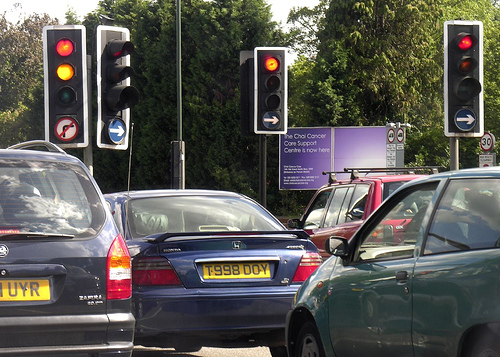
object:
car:
[102, 189, 323, 352]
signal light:
[56, 63, 74, 81]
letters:
[302, 149, 306, 153]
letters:
[8, 282, 16, 296]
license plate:
[203, 262, 272, 279]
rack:
[322, 165, 438, 186]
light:
[106, 233, 131, 300]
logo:
[0, 244, 10, 257]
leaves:
[286, 6, 300, 26]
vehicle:
[0, 147, 136, 356]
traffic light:
[56, 38, 77, 104]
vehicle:
[103, 186, 323, 356]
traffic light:
[94, 20, 137, 155]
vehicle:
[287, 168, 438, 266]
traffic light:
[263, 53, 280, 109]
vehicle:
[282, 167, 499, 357]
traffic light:
[442, 18, 486, 139]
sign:
[278, 122, 405, 190]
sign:
[481, 133, 493, 151]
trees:
[2, 0, 499, 221]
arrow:
[110, 126, 124, 136]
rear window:
[124, 196, 286, 238]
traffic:
[0, 139, 500, 357]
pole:
[171, 0, 185, 188]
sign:
[54, 117, 78, 141]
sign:
[452, 108, 477, 131]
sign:
[264, 116, 280, 125]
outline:
[97, 25, 131, 151]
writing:
[280, 132, 330, 188]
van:
[0, 139, 137, 352]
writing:
[203, 261, 270, 278]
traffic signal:
[41, 24, 91, 152]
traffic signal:
[92, 23, 135, 153]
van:
[281, 167, 498, 357]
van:
[290, 165, 437, 261]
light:
[56, 40, 74, 57]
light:
[263, 53, 278, 71]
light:
[458, 36, 472, 50]